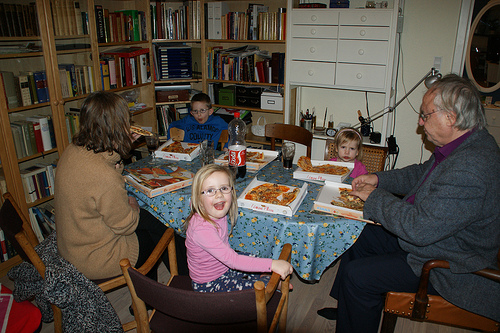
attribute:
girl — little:
[183, 161, 295, 293]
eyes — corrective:
[207, 185, 229, 192]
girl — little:
[178, 160, 299, 287]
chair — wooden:
[124, 221, 299, 331]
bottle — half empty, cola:
[225, 111, 247, 178]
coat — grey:
[336, 114, 498, 331]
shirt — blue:
[166, 112, 228, 146]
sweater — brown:
[1, 218, 106, 332]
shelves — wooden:
[281, 7, 411, 152]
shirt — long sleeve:
[181, 211, 275, 283]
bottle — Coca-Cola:
[215, 104, 258, 166]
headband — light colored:
[339, 126, 360, 134]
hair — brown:
[70, 88, 137, 164]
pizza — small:
[242, 176, 317, 238]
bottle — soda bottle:
[206, 102, 265, 189]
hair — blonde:
[186, 157, 240, 226]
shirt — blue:
[167, 113, 232, 152]